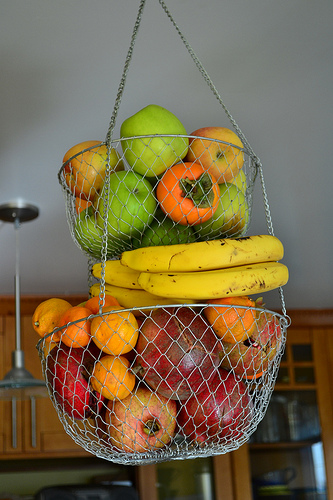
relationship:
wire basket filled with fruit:
[31, 291, 310, 474] [46, 279, 257, 397]